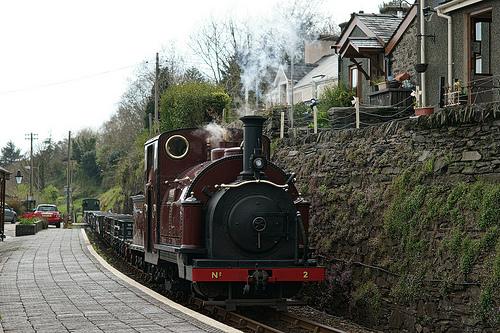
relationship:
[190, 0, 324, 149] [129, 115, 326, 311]
smoke coming from train engine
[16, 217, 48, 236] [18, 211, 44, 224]
planters with flowers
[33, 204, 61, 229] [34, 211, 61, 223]
car has a rear end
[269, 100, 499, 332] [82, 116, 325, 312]
wall next to train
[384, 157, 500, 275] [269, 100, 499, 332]
plants are on wall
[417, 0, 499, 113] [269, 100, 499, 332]
house on top of wall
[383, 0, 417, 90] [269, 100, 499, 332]
house on top of wall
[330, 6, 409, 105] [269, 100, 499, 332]
house on top of wall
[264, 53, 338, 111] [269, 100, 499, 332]
house on top of wall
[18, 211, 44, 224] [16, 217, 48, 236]
flowers are inside planters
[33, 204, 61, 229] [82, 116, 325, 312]
car on left of train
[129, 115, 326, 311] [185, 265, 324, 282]
train engine has a front bumper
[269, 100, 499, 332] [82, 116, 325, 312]
wall on right of train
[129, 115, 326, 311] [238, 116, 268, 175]
train engine has a smoke stack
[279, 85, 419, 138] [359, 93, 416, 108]
fence has wire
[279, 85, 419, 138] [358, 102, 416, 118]
fence has wire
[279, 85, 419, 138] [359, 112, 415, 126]
fence has wire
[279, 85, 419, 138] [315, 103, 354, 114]
fence has wire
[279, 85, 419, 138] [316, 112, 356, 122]
fence has wire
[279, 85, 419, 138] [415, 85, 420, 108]
fence has a post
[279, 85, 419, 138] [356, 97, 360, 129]
fence has a post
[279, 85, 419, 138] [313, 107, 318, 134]
fence has a post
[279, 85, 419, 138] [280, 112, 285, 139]
fence has a post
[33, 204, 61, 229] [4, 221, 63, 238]
car on side of road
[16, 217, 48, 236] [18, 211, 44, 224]
planters have flowers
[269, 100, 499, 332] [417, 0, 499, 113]
wall in front of a house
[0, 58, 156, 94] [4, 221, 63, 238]
wire hung across road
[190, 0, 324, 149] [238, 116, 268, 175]
smoke coming from smoke stack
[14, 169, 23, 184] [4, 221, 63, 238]
street light hanging over road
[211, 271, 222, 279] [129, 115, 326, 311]
word no on train engine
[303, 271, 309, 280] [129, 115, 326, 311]
number 2 on train engine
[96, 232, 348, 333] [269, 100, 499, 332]
train tracks are near wall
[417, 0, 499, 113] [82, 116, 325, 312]
house overlooking train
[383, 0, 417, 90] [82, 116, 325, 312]
house overlooking train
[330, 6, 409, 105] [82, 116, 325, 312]
house overlooking train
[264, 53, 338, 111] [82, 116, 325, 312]
house overlooking train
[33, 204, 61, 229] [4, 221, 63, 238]
car in parking lot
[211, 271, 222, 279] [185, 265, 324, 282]
word no on front bumper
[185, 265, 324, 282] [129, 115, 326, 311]
front bumper on front of train engine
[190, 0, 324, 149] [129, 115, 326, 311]
smoke coming out of train engine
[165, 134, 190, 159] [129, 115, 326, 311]
window on front of train engine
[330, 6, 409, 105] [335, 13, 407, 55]
house has a roof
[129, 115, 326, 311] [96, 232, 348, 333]
train engine on train tracks